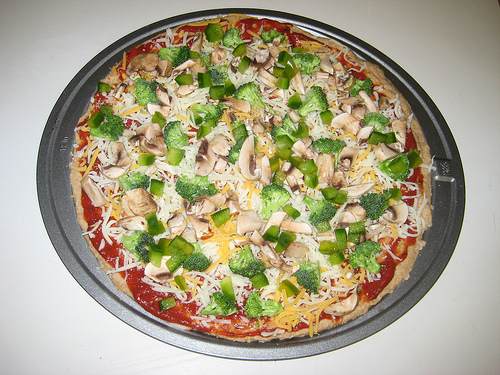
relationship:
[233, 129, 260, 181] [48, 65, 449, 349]
mushroom on pizza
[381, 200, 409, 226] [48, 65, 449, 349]
mushroom on pizza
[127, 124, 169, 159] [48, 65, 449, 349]
mushroom on pizza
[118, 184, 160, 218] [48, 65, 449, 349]
mushroom on pizza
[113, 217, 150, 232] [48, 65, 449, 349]
mushroom on pizza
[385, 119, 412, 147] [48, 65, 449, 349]
mushroom on pizza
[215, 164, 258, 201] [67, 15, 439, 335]
cheese on pizza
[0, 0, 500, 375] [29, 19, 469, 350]
platter/table underneath platter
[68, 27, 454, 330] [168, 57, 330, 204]
sauce on pizza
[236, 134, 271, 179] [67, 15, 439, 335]
mushroom are on top of pizza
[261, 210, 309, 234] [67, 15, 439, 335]
mushroom are on top of pizza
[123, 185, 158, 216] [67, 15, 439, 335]
mushroom are on top of pizza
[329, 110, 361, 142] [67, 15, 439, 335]
mushroom are on top of pizza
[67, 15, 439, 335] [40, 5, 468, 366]
pizza on pan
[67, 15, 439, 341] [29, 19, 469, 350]
pizza on platter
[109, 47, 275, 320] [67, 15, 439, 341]
red sauce on pizza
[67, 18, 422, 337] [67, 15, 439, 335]
sauce covering pizza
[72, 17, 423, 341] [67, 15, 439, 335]
tomato sauce on pizza